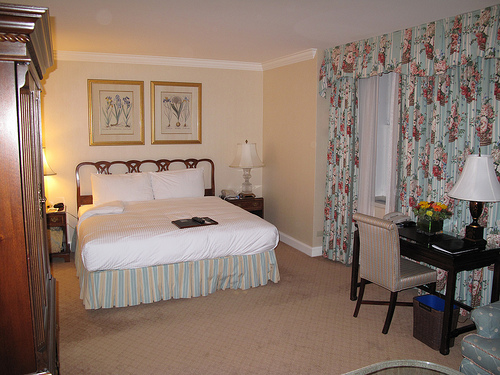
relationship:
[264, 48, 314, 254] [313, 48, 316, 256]
wall has an edge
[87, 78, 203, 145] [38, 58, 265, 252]
pictures are on wall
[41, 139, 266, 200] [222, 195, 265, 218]
lamps on a table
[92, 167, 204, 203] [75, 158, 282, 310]
pillows are on bed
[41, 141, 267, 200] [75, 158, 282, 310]
lamps are on both sides of bed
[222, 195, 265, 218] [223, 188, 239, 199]
nightstand has a telephone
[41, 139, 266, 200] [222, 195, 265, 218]
lamps on stand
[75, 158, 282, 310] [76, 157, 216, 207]
bed has a headboard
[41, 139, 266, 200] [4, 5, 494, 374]
lamps in a bedroom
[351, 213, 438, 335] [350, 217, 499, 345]
chair at a desk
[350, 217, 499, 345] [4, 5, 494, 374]
desk in a bedroom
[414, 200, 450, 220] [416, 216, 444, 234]
flowers are in a pot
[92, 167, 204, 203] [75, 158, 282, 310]
pillows are on a bed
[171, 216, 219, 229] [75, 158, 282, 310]
book sitting on bed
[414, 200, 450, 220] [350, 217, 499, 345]
flowers are on desk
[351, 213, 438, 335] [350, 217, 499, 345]
chair under desk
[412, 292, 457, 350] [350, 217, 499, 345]
trash bin under desk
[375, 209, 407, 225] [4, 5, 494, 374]
phone inside a bedroom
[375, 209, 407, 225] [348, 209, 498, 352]
phone on a desk